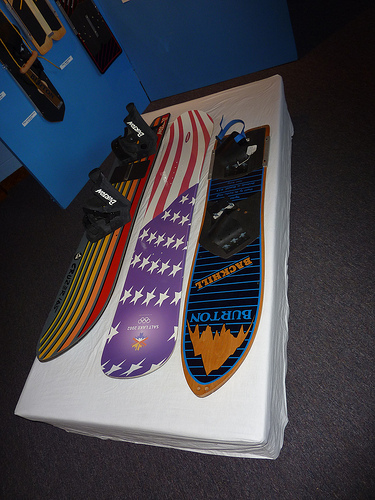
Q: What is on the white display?
A: Snowboards.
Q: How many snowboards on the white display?
A: Three.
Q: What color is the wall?
A: Blue.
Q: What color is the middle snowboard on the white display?
A: Red, white and blue.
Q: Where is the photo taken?
A: A store.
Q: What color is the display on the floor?
A: White.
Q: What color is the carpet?
A: Gray.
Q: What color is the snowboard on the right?
A: Blue and orange.